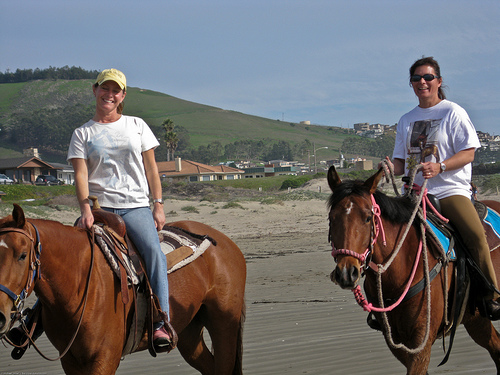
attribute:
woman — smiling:
[62, 64, 177, 350]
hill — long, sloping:
[1, 75, 491, 189]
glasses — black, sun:
[406, 69, 448, 83]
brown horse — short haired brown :
[1, 203, 245, 373]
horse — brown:
[1, 202, 246, 374]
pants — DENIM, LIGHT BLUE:
[98, 207, 172, 329]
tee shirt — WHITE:
[408, 111, 485, 189]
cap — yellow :
[83, 72, 130, 87]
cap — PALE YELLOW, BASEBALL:
[91, 66, 159, 120]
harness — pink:
[330, 183, 448, 310]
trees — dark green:
[2, 63, 104, 81]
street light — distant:
[310, 142, 331, 174]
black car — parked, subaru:
[32, 173, 64, 188]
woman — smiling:
[379, 54, 499, 321]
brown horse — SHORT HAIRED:
[315, 157, 495, 370]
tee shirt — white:
[58, 113, 165, 218]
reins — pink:
[347, 164, 447, 368]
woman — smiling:
[395, 50, 484, 295]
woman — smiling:
[77, 60, 196, 354]